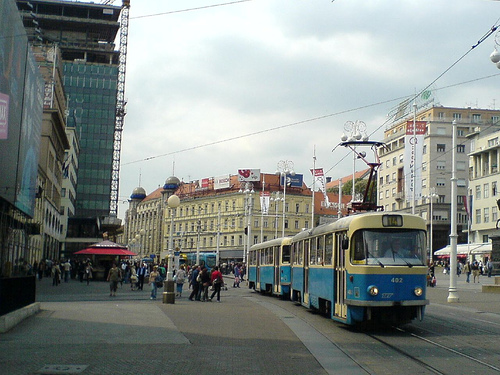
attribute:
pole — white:
[260, 166, 290, 240]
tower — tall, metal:
[109, 64, 121, 223]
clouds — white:
[78, 0, 498, 232]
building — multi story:
[119, 166, 311, 274]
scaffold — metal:
[108, 4, 129, 216]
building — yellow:
[116, 192, 317, 267]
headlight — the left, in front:
[412, 286, 423, 298]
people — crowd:
[86, 205, 267, 316]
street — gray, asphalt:
[3, 265, 495, 372]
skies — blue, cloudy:
[88, 0, 495, 229]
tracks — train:
[325, 332, 455, 372]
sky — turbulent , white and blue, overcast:
[111, 0, 498, 215]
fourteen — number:
[385, 210, 403, 228]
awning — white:
[427, 238, 497, 259]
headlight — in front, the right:
[412, 280, 427, 300]